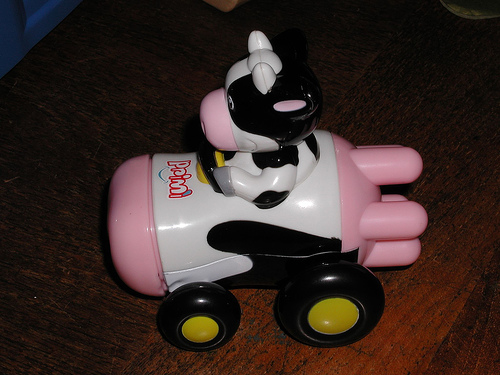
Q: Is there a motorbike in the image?
A: No, there are no motorcycles.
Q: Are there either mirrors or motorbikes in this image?
A: No, there are no motorbikes or mirrors.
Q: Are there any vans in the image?
A: No, there are no vans.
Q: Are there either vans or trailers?
A: No, there are no vans or trailers.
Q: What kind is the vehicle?
A: The vehicle is a car.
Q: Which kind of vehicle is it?
A: The vehicle is a car.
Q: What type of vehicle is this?
A: That is a car.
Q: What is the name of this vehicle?
A: That is a car.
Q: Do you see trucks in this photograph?
A: No, there are no trucks.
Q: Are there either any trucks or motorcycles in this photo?
A: No, there are no trucks or motorcycles.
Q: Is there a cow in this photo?
A: Yes, there is a cow.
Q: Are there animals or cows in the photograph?
A: Yes, there is a cow.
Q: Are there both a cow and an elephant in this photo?
A: No, there is a cow but no elephants.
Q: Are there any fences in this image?
A: No, there are no fences.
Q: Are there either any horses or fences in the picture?
A: No, there are no fences or horses.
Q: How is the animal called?
A: The animal is a cow.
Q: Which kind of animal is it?
A: The animal is a cow.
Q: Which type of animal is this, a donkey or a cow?
A: This is a cow.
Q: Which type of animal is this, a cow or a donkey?
A: This is a cow.